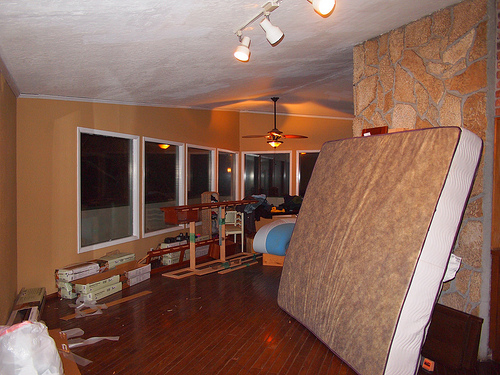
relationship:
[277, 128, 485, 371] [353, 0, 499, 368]
mattress against wall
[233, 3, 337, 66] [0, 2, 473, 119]
lights on ceiling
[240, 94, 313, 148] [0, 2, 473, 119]
fan on ceiling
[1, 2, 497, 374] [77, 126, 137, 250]
room has window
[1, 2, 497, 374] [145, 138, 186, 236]
room has window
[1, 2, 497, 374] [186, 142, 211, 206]
room has window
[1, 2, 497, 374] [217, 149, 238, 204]
room has window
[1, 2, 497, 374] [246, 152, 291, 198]
room has window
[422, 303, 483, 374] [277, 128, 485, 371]
bed frame behind mattress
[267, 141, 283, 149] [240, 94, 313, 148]
light on fan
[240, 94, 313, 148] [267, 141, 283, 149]
fan has light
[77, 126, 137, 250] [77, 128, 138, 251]
window has trim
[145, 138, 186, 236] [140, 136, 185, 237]
window has trim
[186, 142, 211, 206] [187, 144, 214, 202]
window has trim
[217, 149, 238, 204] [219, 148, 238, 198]
window has trim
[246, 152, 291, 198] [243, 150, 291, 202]
window has trim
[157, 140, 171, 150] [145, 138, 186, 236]
light reflection on window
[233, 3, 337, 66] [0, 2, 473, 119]
lights are on ceiling